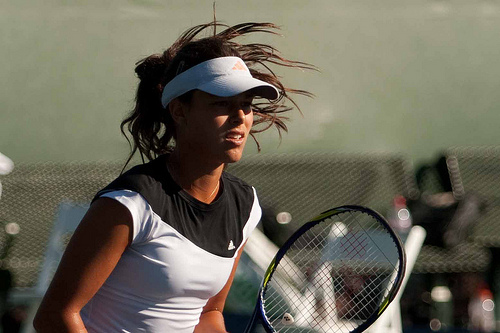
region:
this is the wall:
[326, 31, 406, 72]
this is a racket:
[266, 193, 404, 314]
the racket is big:
[271, 190, 421, 330]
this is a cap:
[161, 54, 286, 101]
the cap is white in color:
[218, 64, 246, 86]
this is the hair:
[218, 25, 268, 49]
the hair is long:
[224, 17, 305, 57]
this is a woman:
[81, 19, 359, 307]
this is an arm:
[65, 201, 115, 298]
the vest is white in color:
[136, 282, 199, 327]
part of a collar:
[193, 196, 220, 233]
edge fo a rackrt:
[371, 210, 434, 268]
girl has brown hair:
[140, 45, 320, 199]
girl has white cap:
[164, 33, 248, 133]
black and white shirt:
[102, 167, 233, 329]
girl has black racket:
[245, 195, 416, 327]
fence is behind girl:
[318, 148, 489, 279]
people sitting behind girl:
[384, 135, 485, 265]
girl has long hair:
[88, 25, 313, 192]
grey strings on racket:
[297, 218, 398, 316]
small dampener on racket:
[272, 308, 297, 329]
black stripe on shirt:
[104, 170, 271, 230]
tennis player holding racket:
[21, 10, 316, 330]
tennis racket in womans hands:
[221, 192, 404, 332]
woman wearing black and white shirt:
[68, 150, 263, 332]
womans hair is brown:
[102, 2, 329, 180]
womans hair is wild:
[98, 4, 328, 179]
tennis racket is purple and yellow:
[231, 200, 421, 331]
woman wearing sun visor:
[151, 53, 281, 109]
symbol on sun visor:
[225, 56, 252, 74]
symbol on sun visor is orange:
[228, 57, 248, 75]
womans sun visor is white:
[148, 50, 285, 112]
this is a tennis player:
[110, 42, 260, 328]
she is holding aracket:
[288, 194, 417, 314]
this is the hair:
[168, 23, 246, 53]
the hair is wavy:
[202, 13, 270, 60]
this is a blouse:
[134, 241, 204, 324]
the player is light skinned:
[198, 116, 226, 141]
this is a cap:
[215, 60, 263, 95]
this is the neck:
[181, 152, 223, 181]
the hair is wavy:
[237, 20, 281, 49]